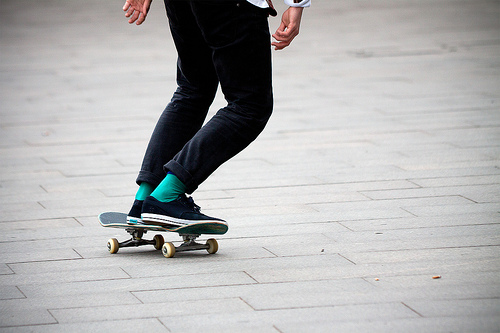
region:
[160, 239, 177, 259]
a wheel on a skateboard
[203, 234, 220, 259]
a wheel on a skateboard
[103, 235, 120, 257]
a wheel on a skateboard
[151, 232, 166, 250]
a wheel on a skateboard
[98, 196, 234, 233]
two feet on a skateboard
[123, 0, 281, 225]
the legs of a person riding a skateboard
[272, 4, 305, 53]
the hand of a person riding a skateboard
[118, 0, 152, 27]
the hand of a person riding a skateboard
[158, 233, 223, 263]
the front wheels of a skateboard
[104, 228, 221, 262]
the four wheels of a skateboard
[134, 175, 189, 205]
the socks are green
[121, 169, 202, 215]
the socks are green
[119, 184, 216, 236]
the sneakers are black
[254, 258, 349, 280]
brick on the walkway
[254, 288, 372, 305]
brick on the walkway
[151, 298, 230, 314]
brick on the walkway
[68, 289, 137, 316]
brick on the walkway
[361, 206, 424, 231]
brick on the walkway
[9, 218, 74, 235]
brick on the walkway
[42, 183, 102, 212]
brick on the walkway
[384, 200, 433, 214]
brick on the walkway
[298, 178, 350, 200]
brick on the walkway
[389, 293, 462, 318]
brick on the walkway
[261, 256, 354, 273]
tile on the walkway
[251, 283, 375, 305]
tile on the walkway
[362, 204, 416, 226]
tile on the walkway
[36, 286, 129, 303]
tile on the walkway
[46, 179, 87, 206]
tile on the walkway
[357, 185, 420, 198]
tile on the walkway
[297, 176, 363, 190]
tile on the walkway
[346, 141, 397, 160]
tile on the walkway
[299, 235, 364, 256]
tile on the walkway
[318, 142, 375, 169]
tile on the walkway